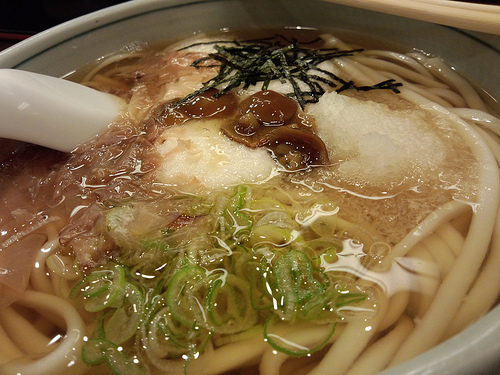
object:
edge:
[0, 0, 201, 69]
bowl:
[0, 0, 500, 375]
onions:
[306, 207, 342, 238]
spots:
[115, 345, 125, 352]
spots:
[363, 325, 374, 332]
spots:
[307, 352, 312, 358]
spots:
[271, 350, 277, 355]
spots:
[212, 302, 219, 308]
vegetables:
[65, 184, 382, 374]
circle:
[0, 288, 92, 375]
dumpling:
[152, 106, 284, 194]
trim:
[0, 0, 208, 69]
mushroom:
[263, 124, 330, 173]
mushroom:
[220, 86, 299, 148]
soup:
[0, 15, 499, 373]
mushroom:
[150, 81, 240, 128]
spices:
[276, 50, 311, 112]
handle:
[0, 63, 134, 169]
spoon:
[0, 61, 131, 159]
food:
[2, 26, 497, 373]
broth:
[0, 22, 500, 374]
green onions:
[204, 279, 244, 325]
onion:
[262, 315, 337, 358]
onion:
[262, 306, 340, 360]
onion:
[164, 264, 206, 332]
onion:
[144, 301, 215, 374]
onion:
[82, 264, 124, 314]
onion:
[79, 331, 113, 367]